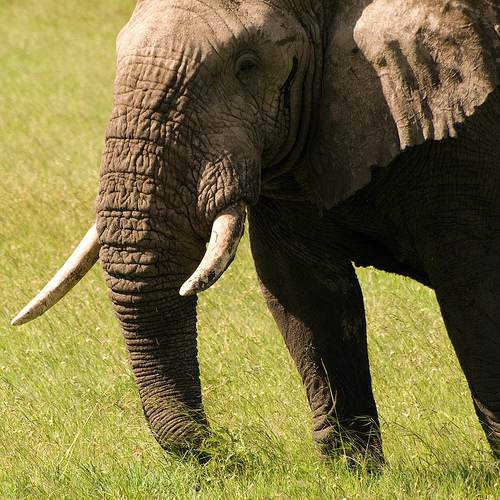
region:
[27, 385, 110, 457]
the grass is green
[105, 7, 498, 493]
the elephant is standing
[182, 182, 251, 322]
the elephant has ivory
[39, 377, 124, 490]
the grass is long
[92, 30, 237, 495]
the nose is long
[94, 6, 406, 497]
the elephant has wrinkles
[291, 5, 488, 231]
the ears are big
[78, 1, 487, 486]
the elephant is gray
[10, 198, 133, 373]
the tusk is pointy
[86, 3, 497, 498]
Elephant is stand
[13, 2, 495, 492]
Elephant is on a green field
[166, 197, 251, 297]
Right tusk of elephant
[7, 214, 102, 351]
Left tusk of elephant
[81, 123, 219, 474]
Trunk of elephant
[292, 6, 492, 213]
Big ear of elephant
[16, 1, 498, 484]
Elephant is brown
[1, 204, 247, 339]
Tusks of elephant are white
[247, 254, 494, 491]
Front legs of elephant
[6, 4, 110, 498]
Field is cover with green grass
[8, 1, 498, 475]
Front view of an elephant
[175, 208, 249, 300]
Left tusk of the elephant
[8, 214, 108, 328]
Right tusk of the elephant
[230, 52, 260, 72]
Left eye of the elephant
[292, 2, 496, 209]
Left ear of the elephant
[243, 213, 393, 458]
Right arm of the elephant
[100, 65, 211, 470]
Elephant horn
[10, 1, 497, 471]
The elephant is currently at rest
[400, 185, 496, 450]
Section of the left arm of the elephant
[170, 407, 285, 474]
Small patch of grass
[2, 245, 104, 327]
The left tusk of the elephant standing in the grass.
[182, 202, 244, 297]
The right tusk on the elephant.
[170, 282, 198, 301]
Tip of the right tusk.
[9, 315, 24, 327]
Tip of the left tusk.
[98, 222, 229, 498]
The elephant's trunk.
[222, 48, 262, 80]
The elephant's small eye.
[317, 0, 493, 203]
The elephant's big floppy ear.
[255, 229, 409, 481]
The elephant's left leg.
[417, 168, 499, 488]
The elephant's right leg.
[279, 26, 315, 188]
The wrinkles to the right of the elephant's eye.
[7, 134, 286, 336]
elephant has two tusks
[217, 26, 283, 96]
elephant has one eye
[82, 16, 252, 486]
elephant has large trunk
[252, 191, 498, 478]
elephant has muddle legs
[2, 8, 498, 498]
grass is light green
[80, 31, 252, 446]
elephant has wrinkly skin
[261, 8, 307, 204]
elephant has mud on face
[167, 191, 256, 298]
elephant has mud on tusks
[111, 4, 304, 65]
elephant has white skin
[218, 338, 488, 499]
elephant stands in grass